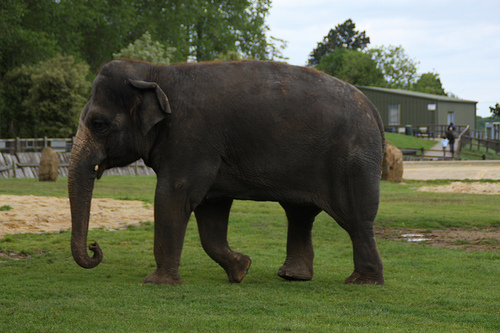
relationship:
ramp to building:
[429, 133, 465, 177] [348, 70, 485, 151]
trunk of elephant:
[37, 125, 144, 291] [48, 44, 430, 310]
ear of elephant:
[121, 76, 173, 160] [63, 55, 388, 288]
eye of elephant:
[86, 112, 106, 140] [51, 50, 371, 275]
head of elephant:
[57, 50, 173, 178] [23, 36, 433, 308]